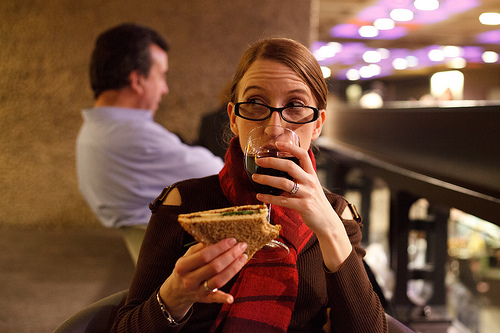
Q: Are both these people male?
A: No, they are both male and female.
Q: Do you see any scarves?
A: Yes, there is a scarf.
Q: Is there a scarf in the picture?
A: Yes, there is a scarf.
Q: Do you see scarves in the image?
A: Yes, there is a scarf.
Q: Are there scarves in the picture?
A: Yes, there is a scarf.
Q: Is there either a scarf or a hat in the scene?
A: Yes, there is a scarf.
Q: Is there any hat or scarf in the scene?
A: Yes, there is a scarf.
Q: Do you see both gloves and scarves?
A: No, there is a scarf but no gloves.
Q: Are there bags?
A: No, there are no bags.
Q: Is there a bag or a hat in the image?
A: No, there are no bags or hats.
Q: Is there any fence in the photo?
A: No, there are no fences.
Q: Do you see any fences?
A: No, there are no fences.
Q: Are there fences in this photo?
A: No, there are no fences.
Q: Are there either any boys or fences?
A: No, there are no fences or boys.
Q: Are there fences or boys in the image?
A: No, there are no fences or boys.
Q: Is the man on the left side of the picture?
A: Yes, the man is on the left of the image.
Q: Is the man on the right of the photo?
A: No, the man is on the left of the image.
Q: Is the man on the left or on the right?
A: The man is on the left of the image.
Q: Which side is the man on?
A: The man is on the left of the image.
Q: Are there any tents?
A: No, there are no tents.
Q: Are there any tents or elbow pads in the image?
A: No, there are no tents or elbow pads.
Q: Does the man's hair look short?
A: Yes, the hair is short.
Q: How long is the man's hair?
A: The hair is short.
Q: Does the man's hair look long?
A: No, the hair is short.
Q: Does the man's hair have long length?
A: No, the hair is short.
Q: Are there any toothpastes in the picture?
A: No, there are no toothpastes.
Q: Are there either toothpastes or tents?
A: No, there are no toothpastes or tents.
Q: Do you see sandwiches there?
A: Yes, there is a sandwich.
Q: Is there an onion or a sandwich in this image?
A: Yes, there is a sandwich.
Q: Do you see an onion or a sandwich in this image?
A: Yes, there is a sandwich.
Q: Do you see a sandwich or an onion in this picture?
A: Yes, there is a sandwich.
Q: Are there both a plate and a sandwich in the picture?
A: No, there is a sandwich but no plates.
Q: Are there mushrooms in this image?
A: No, there are no mushrooms.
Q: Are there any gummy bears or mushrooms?
A: No, there are no mushrooms or gummy bears.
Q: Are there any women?
A: Yes, there is a woman.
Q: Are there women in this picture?
A: Yes, there is a woman.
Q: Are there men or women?
A: Yes, there is a woman.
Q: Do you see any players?
A: No, there are no players.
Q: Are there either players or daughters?
A: No, there are no players or daughters.